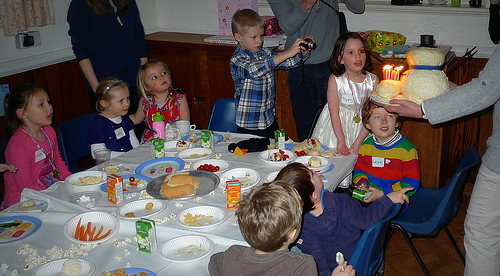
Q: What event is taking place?
A: Birthday party.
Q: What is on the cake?
A: Candles.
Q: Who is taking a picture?
A: Boy at the head of the table.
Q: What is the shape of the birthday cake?
A: Snowman.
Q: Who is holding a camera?
A: Boy in blue shirt.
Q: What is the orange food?
A: Carrots.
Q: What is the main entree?
A: Hot dog.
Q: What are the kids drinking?
A: Juice boxes.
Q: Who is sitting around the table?
A: Children.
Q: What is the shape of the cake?
A: Snowman.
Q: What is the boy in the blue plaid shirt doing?
A: Taking a picture of the cake.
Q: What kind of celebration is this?
A: Birthday.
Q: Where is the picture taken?
A: In the dining room.